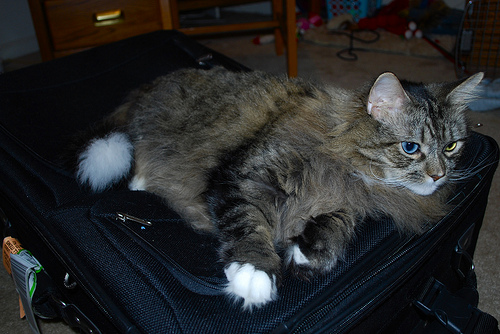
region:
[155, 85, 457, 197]
A cat lying on a suitcase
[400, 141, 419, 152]
Eye of cat reflecting blue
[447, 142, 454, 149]
Eye of cat reflecting yellow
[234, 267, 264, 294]
White fur on the paw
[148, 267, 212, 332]
A suitcase on the ground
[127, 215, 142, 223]
A zipper handle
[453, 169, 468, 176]
The whiskers of the cat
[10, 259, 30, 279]
A label on the suitcase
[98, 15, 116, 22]
A shiny drawer handle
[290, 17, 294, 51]
The wooden leg of a desk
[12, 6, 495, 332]
a kitty is lying on a suit case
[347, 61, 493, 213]
the cat has a blue eye and a yellow eye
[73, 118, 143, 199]
the cat's tail tip is fluffy white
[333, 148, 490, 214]
the cat's whiskers are white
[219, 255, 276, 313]
the cat's paw is fluffy white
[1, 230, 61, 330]
tags are on the suitcase handle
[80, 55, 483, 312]
the cat is a tabby mix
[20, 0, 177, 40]
a wooden drawer is behind the suit case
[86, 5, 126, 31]
a brass handle is on the drawer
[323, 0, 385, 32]
a blue crate is on the floor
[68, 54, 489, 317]
cat lying on suitcase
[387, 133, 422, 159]
blue cat eye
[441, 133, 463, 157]
yellow cat eye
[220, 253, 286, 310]
white cat paw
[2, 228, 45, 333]
tag on suitcase handle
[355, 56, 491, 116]
two cat ears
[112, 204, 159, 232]
zipper clasp on suitcase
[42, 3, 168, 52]
wooden drawer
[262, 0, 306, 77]
two wooden chair legs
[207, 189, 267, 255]
black stripes on cat leg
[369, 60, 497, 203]
the head of a cat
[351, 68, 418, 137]
the ear of a cat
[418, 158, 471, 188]
the nose of a cat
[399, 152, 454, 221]
the mouth of a cat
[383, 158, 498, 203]
the whiskers of a cat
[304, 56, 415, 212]
the neck of a cat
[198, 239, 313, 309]
the paw of a cat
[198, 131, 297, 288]
the leg of a cat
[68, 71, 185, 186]
the tail of a cat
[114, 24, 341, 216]
the body of a cat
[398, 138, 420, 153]
A cat's blue eye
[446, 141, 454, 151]
A cat's yellow eye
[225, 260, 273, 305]
The white paw of a cat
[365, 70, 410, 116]
A cat's ear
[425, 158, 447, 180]
The nose of a cat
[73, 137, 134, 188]
The white tip of a cat's tail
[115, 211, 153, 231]
A metal zipper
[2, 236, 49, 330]
Tags on the side of a black suitcase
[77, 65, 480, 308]
A cat laying on a black suitcase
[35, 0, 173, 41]
A closed wooden drawer